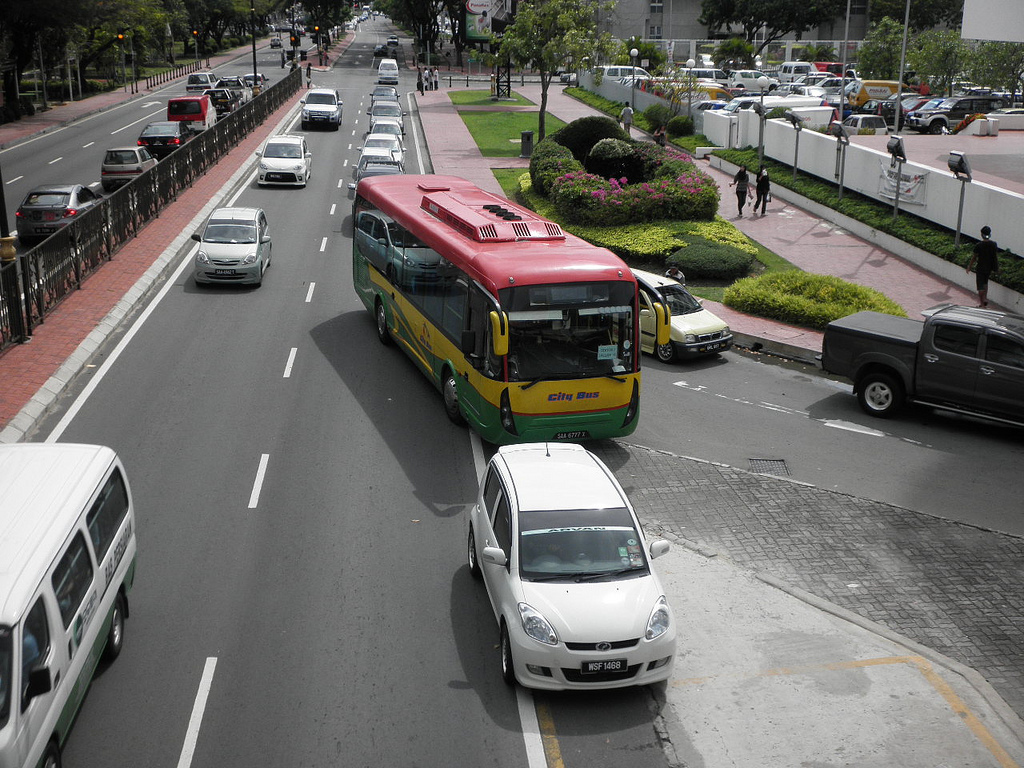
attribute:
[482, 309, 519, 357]
mirrors — yellow